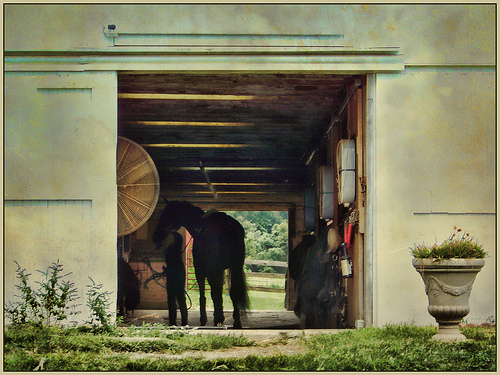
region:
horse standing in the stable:
[153, 196, 270, 328]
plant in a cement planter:
[409, 227, 492, 344]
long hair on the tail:
[224, 235, 256, 318]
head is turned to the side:
[148, 196, 197, 240]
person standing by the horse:
[146, 194, 265, 329]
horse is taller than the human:
[151, 196, 253, 329]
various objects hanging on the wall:
[282, 215, 364, 335]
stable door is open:
[183, 200, 295, 305]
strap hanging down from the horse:
[177, 233, 195, 252]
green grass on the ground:
[3, 315, 498, 372]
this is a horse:
[149, 176, 261, 333]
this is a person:
[149, 202, 191, 320]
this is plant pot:
[391, 225, 498, 337]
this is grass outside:
[363, 318, 425, 372]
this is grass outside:
[303, 306, 355, 369]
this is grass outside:
[222, 340, 238, 371]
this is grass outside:
[71, 313, 88, 355]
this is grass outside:
[15, 347, 89, 369]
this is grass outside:
[127, 347, 206, 370]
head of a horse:
[142, 183, 184, 244]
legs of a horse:
[187, 273, 228, 341]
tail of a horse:
[227, 235, 259, 316]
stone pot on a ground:
[396, 226, 494, 350]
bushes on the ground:
[9, 265, 143, 373]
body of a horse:
[193, 213, 257, 258]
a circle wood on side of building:
[120, 135, 167, 235]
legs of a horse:
[187, 256, 227, 316]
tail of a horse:
[229, 232, 274, 336]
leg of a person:
[155, 275, 195, 336]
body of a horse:
[197, 212, 251, 263]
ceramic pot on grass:
[410, 236, 488, 343]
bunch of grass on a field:
[57, 296, 388, 370]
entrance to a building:
[97, 28, 397, 350]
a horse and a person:
[140, 192, 275, 326]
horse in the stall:
[153, 191, 255, 327]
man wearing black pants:
[154, 260, 194, 329]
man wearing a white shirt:
[154, 228, 186, 260]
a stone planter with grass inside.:
[410, 257, 482, 342]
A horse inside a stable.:
[152, 197, 251, 328]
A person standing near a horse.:
[160, 221, 188, 323]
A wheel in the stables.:
[116, 135, 160, 235]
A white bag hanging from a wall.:
[338, 242, 353, 277]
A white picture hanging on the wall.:
[335, 137, 355, 205]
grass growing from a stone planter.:
[409, 226, 487, 258]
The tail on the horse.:
[225, 234, 250, 305]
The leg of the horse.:
[210, 268, 223, 324]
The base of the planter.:
[429, 318, 468, 343]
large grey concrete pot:
[411, 257, 493, 347]